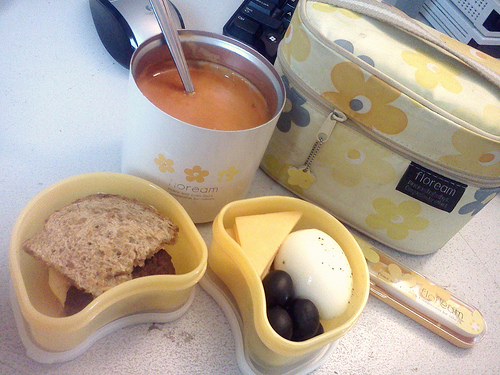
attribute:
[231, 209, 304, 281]
cheese — sliced, triangular, yellow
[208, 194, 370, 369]
container — plastic, yellow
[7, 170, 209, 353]
container — plastic, yellow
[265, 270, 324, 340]
olives — black, dark purple, oval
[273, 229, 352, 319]
boiled egg — white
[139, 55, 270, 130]
soup — tomato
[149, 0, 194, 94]
spoon — silver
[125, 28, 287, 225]
thermos — flowery, metal, white, round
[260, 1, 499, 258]
lunch box — insulated, flowery, flower patterened, floral print, white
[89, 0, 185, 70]
mouse — black, logitech, silver, logiteck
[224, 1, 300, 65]
keyboard — black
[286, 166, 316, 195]
charm — a flower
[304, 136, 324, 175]
chain — silver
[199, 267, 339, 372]
lid — white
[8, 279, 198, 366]
lid — white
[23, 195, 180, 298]
bread — cut, wheat